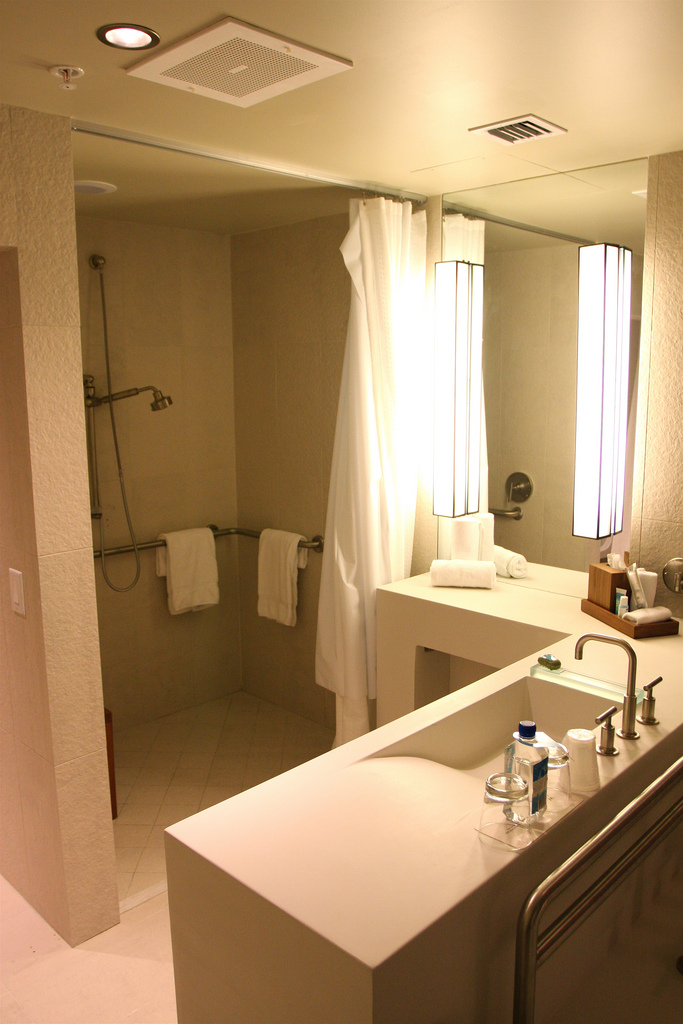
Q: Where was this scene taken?
A: In the bathroom.